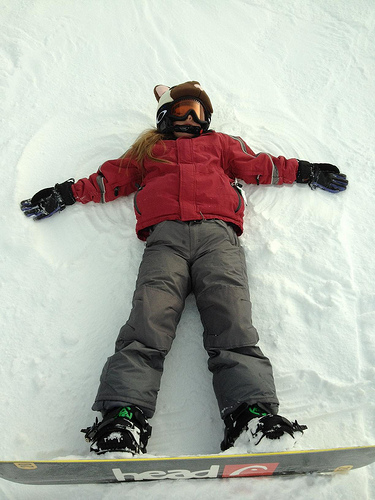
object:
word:
[112, 464, 221, 482]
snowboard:
[0, 443, 372, 485]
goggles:
[166, 98, 210, 126]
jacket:
[71, 131, 299, 241]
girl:
[20, 76, 347, 453]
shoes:
[80, 403, 307, 454]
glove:
[297, 159, 348, 193]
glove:
[21, 180, 74, 221]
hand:
[20, 174, 72, 222]